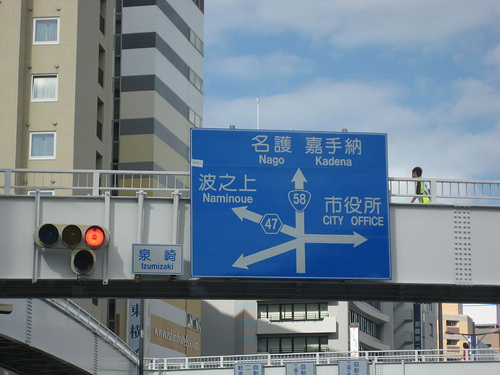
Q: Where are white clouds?
A: In the sky.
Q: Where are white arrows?
A: On blue sign.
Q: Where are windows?
A: On buildings.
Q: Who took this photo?
A: Someone driving.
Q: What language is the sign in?
A: Chinese.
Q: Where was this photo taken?
A: China.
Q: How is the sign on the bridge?
A: It is suspended by bars.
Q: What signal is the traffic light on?
A: It's red for stop.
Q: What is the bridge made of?
A: Steel.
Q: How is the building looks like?
A: Good.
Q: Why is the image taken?
A: Remembrance.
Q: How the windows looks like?
A: Tan.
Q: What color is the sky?
A: Blue.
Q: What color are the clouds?
A: Gray and white.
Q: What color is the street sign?
A: Blue and white.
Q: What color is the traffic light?
A: Red.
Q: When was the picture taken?
A: Daytime.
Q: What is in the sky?
A: Clouds.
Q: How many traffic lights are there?
A: One.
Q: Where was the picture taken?
A: City street.